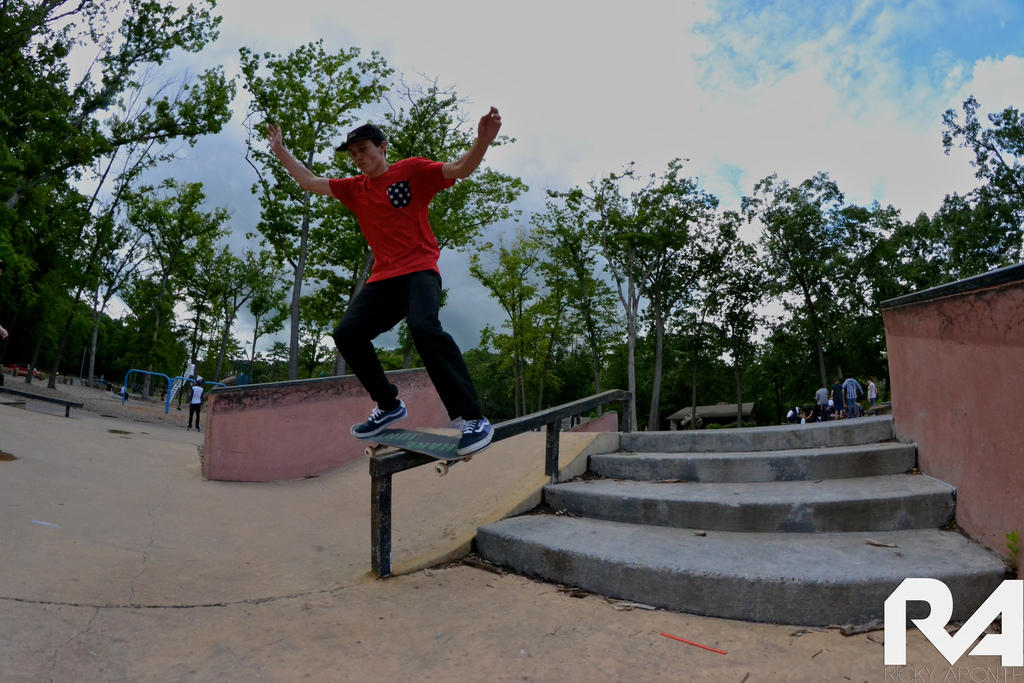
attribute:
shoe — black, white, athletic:
[343, 396, 414, 448]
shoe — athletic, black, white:
[443, 413, 507, 462]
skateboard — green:
[364, 412, 475, 467]